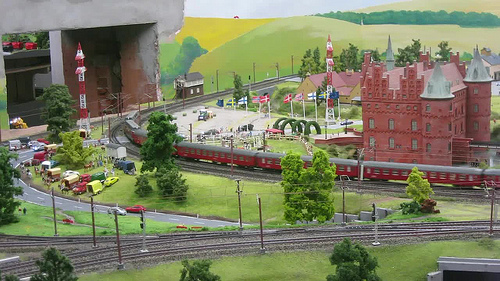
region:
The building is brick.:
[355, 60, 460, 175]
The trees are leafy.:
[274, 152, 339, 222]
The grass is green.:
[145, 238, 432, 280]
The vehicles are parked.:
[27, 141, 113, 200]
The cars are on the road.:
[107, 201, 146, 220]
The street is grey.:
[8, 220, 496, 263]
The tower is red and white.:
[62, 40, 94, 136]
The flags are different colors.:
[209, 87, 345, 103]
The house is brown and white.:
[167, 71, 213, 99]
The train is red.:
[128, 112, 493, 209]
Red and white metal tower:
[70, 41, 95, 142]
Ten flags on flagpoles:
[213, 89, 343, 124]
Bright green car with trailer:
[85, 174, 119, 194]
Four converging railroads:
[1, 217, 498, 279]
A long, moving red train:
[123, 117, 497, 188]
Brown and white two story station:
[174, 70, 205, 97]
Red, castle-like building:
[358, 40, 493, 164]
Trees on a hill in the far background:
[311, 10, 498, 29]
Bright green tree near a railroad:
[279, 148, 336, 225]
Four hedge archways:
[275, 115, 322, 134]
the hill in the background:
[196, 22, 375, 82]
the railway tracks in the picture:
[6, 224, 499, 259]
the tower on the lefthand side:
[77, 41, 95, 136]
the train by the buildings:
[128, 108, 496, 198]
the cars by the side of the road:
[38, 155, 127, 202]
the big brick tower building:
[365, 64, 486, 164]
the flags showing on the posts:
[233, 78, 335, 116]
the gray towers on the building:
[431, 58, 498, 107]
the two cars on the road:
[111, 204, 148, 219]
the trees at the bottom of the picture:
[56, 89, 448, 239]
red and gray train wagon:
[179, 141, 257, 173]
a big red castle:
[356, 58, 492, 165]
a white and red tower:
[75, 42, 93, 137]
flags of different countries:
[221, 94, 332, 106]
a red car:
[127, 203, 147, 215]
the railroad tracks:
[150, 227, 342, 250]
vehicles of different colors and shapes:
[36, 153, 120, 202]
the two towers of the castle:
[421, 56, 491, 167]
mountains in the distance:
[186, 3, 498, 40]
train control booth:
[176, 67, 204, 99]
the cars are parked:
[46, 158, 129, 204]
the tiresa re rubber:
[266, 109, 326, 138]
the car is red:
[122, 198, 157, 213]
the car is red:
[72, 179, 90, 199]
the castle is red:
[351, 59, 488, 161]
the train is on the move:
[197, 138, 288, 178]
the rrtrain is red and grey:
[215, 144, 260, 158]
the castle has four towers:
[351, 38, 480, 163]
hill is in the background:
[264, 16, 332, 52]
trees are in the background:
[369, 6, 474, 27]